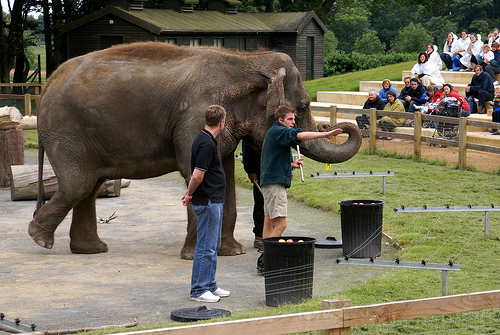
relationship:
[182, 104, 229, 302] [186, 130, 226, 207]
man wearing polo shirt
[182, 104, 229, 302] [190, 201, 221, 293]
man wearing jeans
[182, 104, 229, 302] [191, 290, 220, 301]
man wearing sneaker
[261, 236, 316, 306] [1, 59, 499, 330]
barrel on ground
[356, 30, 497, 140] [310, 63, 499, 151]
crowd sitting on benches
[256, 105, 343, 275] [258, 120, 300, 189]
man wearing sweater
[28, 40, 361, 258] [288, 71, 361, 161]
elephant has trunk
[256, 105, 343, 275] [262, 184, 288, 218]
man wearing shorts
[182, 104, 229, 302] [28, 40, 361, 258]
man beside elephant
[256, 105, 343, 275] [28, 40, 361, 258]
man beside elephant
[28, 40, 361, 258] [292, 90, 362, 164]
elephant has trunk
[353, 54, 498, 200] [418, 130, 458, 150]
people are sitting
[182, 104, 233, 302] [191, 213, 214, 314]
man wearing blue jeans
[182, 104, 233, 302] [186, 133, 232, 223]
man wearing black polo shirt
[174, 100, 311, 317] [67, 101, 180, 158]
two men standing near elephant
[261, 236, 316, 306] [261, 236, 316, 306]
barrel black garbage barrel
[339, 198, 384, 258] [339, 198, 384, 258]
barrel black garbage barrel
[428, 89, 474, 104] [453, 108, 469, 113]
person wearing red shirt